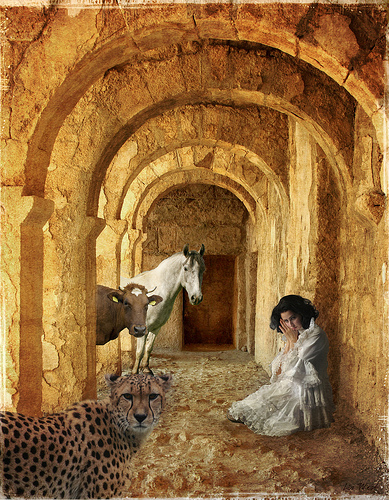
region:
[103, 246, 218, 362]
horse and cow in painting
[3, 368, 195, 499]
leopard looking straight ahead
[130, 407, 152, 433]
nose of the leopard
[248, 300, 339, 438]
lady in white dress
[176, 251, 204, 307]
head of white horse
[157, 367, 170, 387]
ear of the leopard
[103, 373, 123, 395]
ear of the leopard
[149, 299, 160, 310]
tag in cow's ear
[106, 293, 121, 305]
tag in cow's ear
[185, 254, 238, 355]
back opening of space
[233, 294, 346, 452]
Lady in white lace dress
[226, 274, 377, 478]
lady in white sitting on dirt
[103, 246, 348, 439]
lady with animals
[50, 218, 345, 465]
Animals with woman sitting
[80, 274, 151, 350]
A brown cow with horns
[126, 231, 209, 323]
White horse with brown cow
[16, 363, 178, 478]
Cheetah looking at camera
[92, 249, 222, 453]
A cheetah a cow and a horse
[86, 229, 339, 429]
Woman with a cheetah, a cow and a horse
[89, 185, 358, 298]
Old stone structure is sand colored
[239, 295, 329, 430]
a women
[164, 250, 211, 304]
the horse is white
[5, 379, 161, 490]
a cheetah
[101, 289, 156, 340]
a brown cow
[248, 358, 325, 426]
the women is wearing a white dress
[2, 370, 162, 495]
the cheetah is orange and black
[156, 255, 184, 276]
the horses hair is white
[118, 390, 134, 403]
the eye of the cheetah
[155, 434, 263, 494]
the sand is brown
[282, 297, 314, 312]
the womens hair is black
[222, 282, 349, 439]
This is a person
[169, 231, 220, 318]
Head of a horse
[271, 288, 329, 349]
Head of a person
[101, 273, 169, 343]
Head of a cow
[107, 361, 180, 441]
Head of a cheater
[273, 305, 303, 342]
Face of a person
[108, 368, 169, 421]
Face of a cheater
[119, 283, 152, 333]
Face of a cow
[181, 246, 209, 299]
Face of a horse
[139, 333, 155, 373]
Leg of a horse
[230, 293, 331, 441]
brunette woman in white ruffled dress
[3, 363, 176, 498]
cheetah with calm expression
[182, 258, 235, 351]
door of something like a closet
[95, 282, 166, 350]
brown cow with curved horn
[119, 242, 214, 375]
white horse with touch of brown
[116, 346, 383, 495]
uneven clay floor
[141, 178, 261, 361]
arch nearest door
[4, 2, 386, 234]
multiple round arches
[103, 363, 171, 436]
place where horses leg blend with cheetah's head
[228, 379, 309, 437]
skirt of white dress